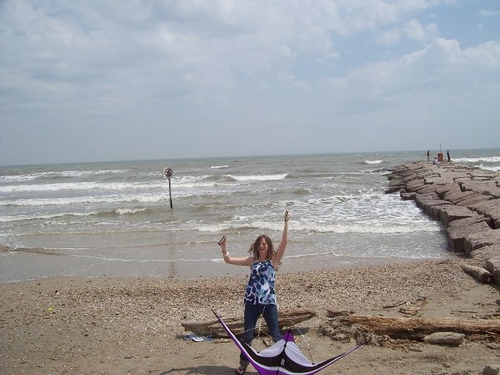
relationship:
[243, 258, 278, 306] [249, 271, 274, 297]
pattern on shirt.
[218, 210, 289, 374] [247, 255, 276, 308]
woman wearing shirt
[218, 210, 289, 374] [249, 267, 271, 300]
woman wearing print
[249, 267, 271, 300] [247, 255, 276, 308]
print on shirt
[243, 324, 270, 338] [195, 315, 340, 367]
string on kite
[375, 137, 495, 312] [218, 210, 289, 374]
jetty next to woman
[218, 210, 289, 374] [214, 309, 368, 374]
woman holding kite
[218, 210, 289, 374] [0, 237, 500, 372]
woman standing on beach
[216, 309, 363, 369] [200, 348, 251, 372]
kite on ground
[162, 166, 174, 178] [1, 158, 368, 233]
sign in water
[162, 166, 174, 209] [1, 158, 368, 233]
sign in water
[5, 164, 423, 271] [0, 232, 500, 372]
water on shore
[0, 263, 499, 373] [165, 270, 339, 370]
sand at beach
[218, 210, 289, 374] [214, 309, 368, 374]
woman holding handles of kite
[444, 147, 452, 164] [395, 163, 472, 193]
person standing on rocks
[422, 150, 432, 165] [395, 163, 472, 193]
person standing on rocks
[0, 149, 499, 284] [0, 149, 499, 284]
water of water